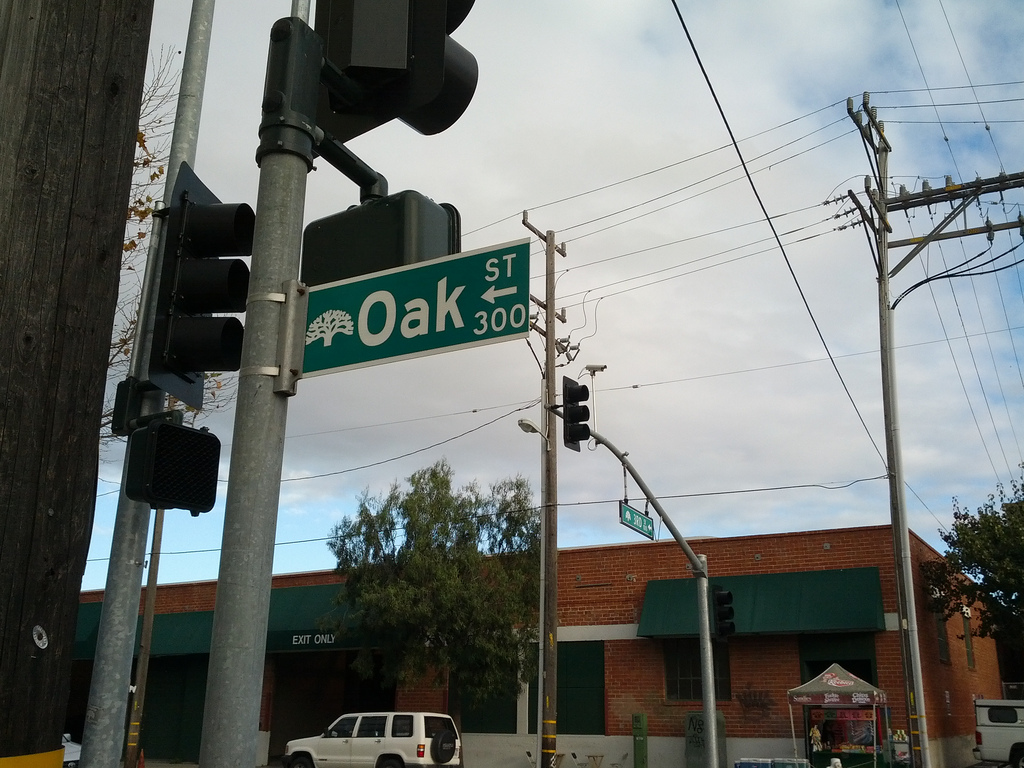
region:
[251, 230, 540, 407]
green and white oak street sign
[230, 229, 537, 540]
green and white oak street sign on pole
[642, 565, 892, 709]
green awning over brick building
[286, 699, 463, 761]
white truck in front of brick building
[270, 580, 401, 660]
green awning withe white letters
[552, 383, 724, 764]
black street sign on metal pole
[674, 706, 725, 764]
green trash can against metal building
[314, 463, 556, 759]
green tree against brick building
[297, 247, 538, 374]
green street sign on pole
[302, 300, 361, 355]
white tree drawing on sign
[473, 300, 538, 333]
white number on sign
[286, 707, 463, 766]
white truck parked on street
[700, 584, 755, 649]
black traffic signal on pole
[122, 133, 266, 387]
a black traffic signal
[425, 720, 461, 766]
tire on back of truck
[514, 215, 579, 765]
pole with power lines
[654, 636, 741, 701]
windows on the building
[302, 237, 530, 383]
the street sign is green and white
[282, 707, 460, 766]
the suv is white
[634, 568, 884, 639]
the awning is dark green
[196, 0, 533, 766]
the sign hanging from the pole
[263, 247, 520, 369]
green and white strdet sign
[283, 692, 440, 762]
white car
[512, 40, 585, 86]
white clouds in blue sky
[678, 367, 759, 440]
white clouds in blue sky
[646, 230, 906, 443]
white clouds in blue sky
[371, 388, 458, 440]
white clouds in blue sky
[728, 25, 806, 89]
white clouds in blue sky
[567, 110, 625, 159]
white clouds in blue sky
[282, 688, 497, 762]
white SUV with spare tire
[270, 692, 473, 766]
white SUV with spare tire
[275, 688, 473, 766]
white SUV with spare tire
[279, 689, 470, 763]
white SUV with spare tire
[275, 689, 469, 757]
white SUV with spare tire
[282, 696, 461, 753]
white SUV with spare tire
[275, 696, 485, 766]
white SUV with spare tire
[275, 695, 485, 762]
white SUV with spare tire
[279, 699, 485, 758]
white SUV with spare tire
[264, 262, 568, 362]
The sign is green and white.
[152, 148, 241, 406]
A traffic signal on the pole.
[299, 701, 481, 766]
A white truck is parked in front of the building.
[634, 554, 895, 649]
A green canopy over the door.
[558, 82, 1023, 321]
Wires hanging on the pole.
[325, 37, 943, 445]
The sky is white and blue.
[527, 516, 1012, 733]
The building is made of brick.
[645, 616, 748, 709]
A window on the building.